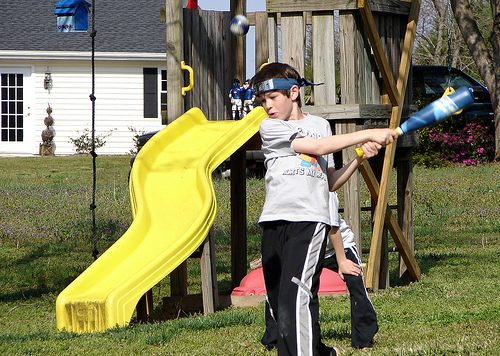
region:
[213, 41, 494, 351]
a boy swinging a bat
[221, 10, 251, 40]
a blue and silver ball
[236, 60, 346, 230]
a boy wearing a t-shirt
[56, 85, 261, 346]
a yellow slide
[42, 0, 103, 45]
a blue birdhouse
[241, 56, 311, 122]
a boy wearing a blue head band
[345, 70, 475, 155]
a blue and white bat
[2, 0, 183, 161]
a white house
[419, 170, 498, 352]
brown and green grass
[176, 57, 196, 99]
a yellow handle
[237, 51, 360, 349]
A boy with a bandana around his head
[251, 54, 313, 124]
The boy has dark brown hair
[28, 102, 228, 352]
A yellow slipper slide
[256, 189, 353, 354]
Jogging pants that are black gray and white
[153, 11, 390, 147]
A wooden fort with a slide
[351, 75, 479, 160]
A blue bat swinging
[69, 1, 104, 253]
A rope for climbing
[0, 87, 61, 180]
A decorative tree by the door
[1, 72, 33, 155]
The door has fifteen windows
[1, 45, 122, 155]
The house is white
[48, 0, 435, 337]
A playset.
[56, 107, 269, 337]
A yellow slide.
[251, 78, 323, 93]
A blue bandana.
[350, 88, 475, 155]
A blue baseball bat with a yellow handle.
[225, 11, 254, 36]
A baseball.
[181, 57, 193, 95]
A yellow handle.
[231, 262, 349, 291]
A red lid.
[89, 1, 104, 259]
A black rope with knots in it.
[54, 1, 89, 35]
A blue birdhouse.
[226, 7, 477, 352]
A boy swinging a baseball bat.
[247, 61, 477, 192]
A boy is swinging a bat.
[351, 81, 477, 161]
A bat's colors are blue, white, and yellow.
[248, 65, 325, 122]
A boy is wearing a headband.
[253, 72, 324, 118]
The colors of a headband are blue and white.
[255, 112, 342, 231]
The color of a boy's shirt is white, blue, yellow, and orange.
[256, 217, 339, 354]
The colors of a boy's pants are black and white.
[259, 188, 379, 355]
A boy is crouching behind another boy.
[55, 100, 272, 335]
The color of a slide is yellow.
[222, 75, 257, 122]
Two toys are sitting on top of a slide.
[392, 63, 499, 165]
A vehicle is in the background.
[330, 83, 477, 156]
a blue and yellow bat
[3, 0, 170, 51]
the rooftop of a house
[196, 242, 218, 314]
a gray wooden pole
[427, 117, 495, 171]
a bush of purple flowers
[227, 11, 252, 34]
a blue and gray ball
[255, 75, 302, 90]
a blue headband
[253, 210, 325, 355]
a boy's black and gray pants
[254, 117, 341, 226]
a boy's gray shirt